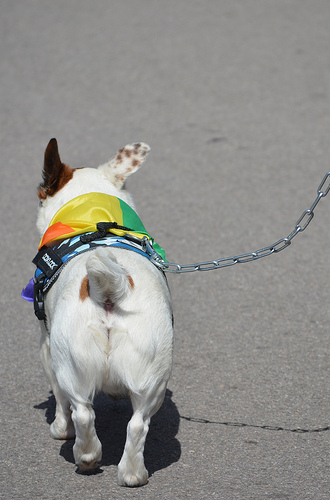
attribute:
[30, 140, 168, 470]
dog — small, walking, brown, white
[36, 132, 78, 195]
ear — brown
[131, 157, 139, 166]
spots — brown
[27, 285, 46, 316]
buckle — plastic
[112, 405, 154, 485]
dog's leg —  dog's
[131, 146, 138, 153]
spot — brown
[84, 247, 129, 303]
tail — white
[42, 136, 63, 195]
ear — brown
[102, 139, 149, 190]
ear — brown, spotted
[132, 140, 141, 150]
spot — brown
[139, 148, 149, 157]
spot — brown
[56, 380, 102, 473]
leg — rear leg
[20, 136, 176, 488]
dog — walking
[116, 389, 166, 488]
leg — rear leg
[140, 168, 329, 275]
chain —   dog's